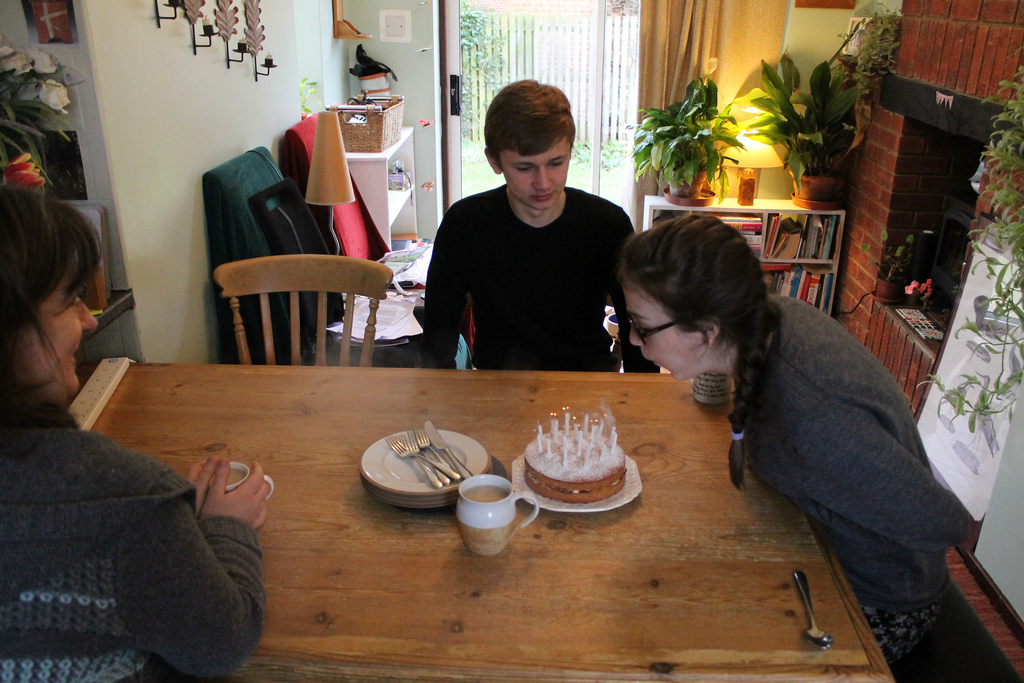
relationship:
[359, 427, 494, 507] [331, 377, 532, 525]
plates of plates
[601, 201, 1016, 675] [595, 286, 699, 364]
girl wearing glasses